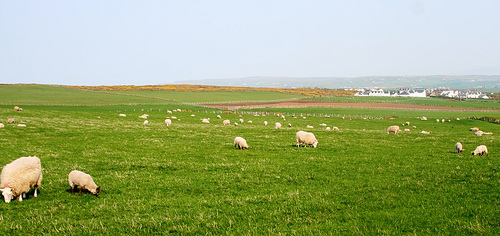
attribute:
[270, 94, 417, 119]
land — ready for planting, tilled 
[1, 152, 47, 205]
sheep — present, white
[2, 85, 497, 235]
pasture — green, grass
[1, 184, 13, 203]
face — white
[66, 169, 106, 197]
sheep — grazing, small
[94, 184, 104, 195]
face — black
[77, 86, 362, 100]
grass — yellow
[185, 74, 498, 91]
mountain — in background, soft, rolling, green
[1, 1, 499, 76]
sky — blue, hazy, present, sunny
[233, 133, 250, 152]
sheep — small, eating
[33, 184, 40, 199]
leg — white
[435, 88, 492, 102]
houses — in a local town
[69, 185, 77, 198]
leg — black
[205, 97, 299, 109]
road —  in the distance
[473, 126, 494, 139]
sheep — laying